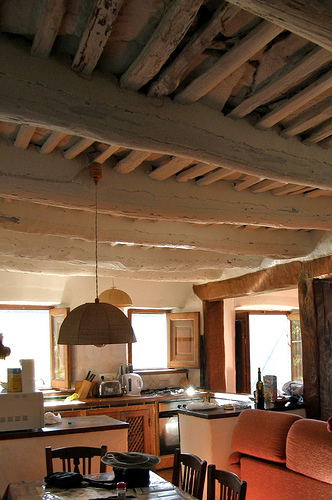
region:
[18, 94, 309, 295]
rustic ceiling of crossed logs and beams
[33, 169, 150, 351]
lighting fixtures hanging from ceiling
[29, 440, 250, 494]
dark wooden chairs pushed under a table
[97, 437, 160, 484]
brimmed hat on corner of table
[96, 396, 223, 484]
kitchen entryway between two counters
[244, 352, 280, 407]
dark bottle and box on countertop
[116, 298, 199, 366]
open window by kitchen corner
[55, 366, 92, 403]
knives in wood block by sink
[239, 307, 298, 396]
bright light coming from doorway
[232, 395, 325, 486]
curved cushions on top of seat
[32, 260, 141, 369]
Light hanging over table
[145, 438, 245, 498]
Chairs around table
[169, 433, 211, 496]
Chairs are dark brown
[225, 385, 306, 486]
Furniture is red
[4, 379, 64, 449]
White microwave on counter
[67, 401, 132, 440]
Counter top is black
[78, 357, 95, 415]
Knives in wood block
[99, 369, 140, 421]
Silver toaster on counter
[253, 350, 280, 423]
Bottle of wine on counter top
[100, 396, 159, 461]
Cupboards are brown and wood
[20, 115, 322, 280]
A wood beam ceiling in house.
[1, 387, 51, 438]
Back of microwave oven sitting on kitchen counter.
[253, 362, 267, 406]
Wine bottle sitting on kitchen counter.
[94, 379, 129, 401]
Toaster sitting on kitchen counter.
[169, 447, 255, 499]
Two brown chairs pushed under table.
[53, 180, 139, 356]
Light with shade hanging from ceiling.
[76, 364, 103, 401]
Wood block for knives sitting on kitchen counter.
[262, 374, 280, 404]
Box of cereal sitting on kitchen counter.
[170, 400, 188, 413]
Two control knobs for stove.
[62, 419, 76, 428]
Green bottle top laying on kitchen counter.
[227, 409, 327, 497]
the back of what appears to be a pink couch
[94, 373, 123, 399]
a metal toaster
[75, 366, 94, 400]
black handles emerging from a knife block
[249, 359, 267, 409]
tall green bottle with a cork in it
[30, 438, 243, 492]
dark brown chairs around a table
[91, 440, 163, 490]
black hat upside down on a table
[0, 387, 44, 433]
microwave seen from the side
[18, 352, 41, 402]
roll of paper towels on microwave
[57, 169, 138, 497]
half-dome shaped light over table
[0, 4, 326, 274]
exposed, partially painted beams in cieling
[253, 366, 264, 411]
a glass bottle on a counter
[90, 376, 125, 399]
a silver toaster on the counter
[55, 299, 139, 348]
a large light fixture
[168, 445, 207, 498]
a brown chair at a table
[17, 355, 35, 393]
a roll of paper towels on the microwave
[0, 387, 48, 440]
a white microwave on the counter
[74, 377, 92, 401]
a wooden knife block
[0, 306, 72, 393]
an open window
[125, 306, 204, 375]
an open window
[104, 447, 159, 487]
a hat on the table